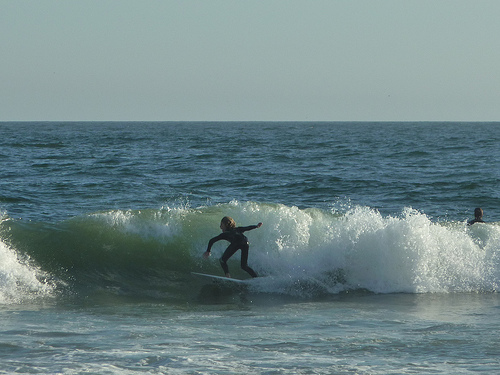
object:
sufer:
[203, 216, 263, 280]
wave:
[0, 208, 499, 301]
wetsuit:
[208, 225, 256, 278]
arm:
[239, 223, 265, 233]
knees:
[218, 254, 227, 263]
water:
[0, 307, 498, 375]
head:
[472, 204, 484, 217]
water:
[1, 120, 496, 374]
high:
[5, 190, 498, 304]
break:
[37, 216, 163, 294]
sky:
[3, 1, 500, 124]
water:
[4, 120, 499, 203]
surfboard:
[188, 272, 246, 285]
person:
[467, 205, 486, 224]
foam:
[335, 199, 367, 224]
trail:
[252, 267, 326, 286]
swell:
[65, 192, 278, 236]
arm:
[203, 234, 224, 256]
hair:
[221, 215, 233, 229]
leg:
[217, 245, 235, 279]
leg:
[240, 247, 258, 280]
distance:
[3, 119, 499, 186]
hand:
[203, 251, 213, 257]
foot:
[251, 273, 263, 281]